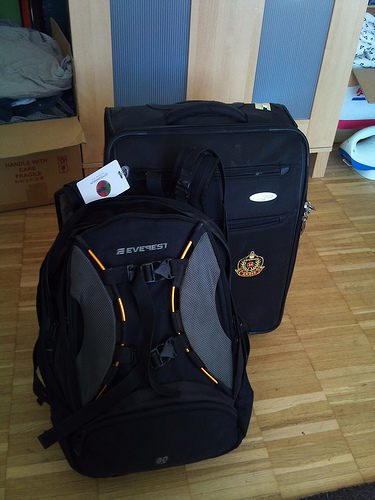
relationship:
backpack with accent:
[34, 193, 255, 477] [85, 244, 128, 322]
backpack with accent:
[34, 193, 255, 477] [160, 230, 221, 398]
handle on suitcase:
[144, 94, 252, 126] [90, 99, 320, 334]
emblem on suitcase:
[228, 244, 269, 282] [90, 99, 320, 334]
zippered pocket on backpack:
[166, 221, 241, 394] [31, 193, 255, 477]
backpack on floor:
[31, 193, 255, 477] [8, 160, 373, 484]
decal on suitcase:
[242, 187, 280, 203] [90, 99, 320, 334]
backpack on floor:
[34, 193, 255, 477] [228, 444, 371, 497]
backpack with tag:
[31, 193, 255, 477] [75, 157, 132, 204]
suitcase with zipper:
[90, 99, 320, 334] [303, 200, 314, 213]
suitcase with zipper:
[90, 99, 320, 334] [302, 213, 307, 232]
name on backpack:
[115, 241, 169, 255] [31, 193, 255, 477]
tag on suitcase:
[81, 163, 138, 205] [93, 99, 315, 333]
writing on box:
[6, 149, 64, 194] [0, 114, 86, 214]